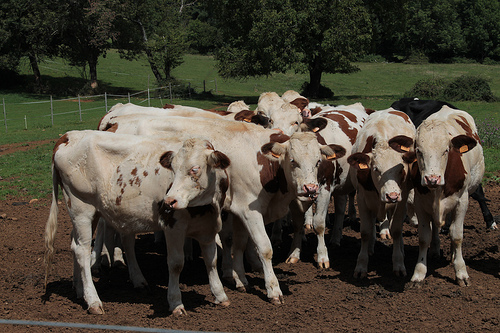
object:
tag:
[458, 145, 468, 154]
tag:
[401, 143, 411, 152]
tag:
[359, 163, 369, 169]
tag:
[325, 151, 337, 160]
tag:
[312, 127, 321, 132]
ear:
[453, 134, 478, 154]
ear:
[388, 135, 416, 154]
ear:
[347, 153, 371, 171]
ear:
[319, 145, 347, 163]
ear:
[302, 116, 327, 132]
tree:
[253, 0, 371, 100]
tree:
[116, 0, 207, 99]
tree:
[45, 0, 126, 91]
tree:
[0, 0, 67, 88]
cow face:
[166, 142, 209, 211]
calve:
[232, 92, 318, 131]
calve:
[99, 111, 331, 306]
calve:
[345, 107, 417, 280]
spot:
[130, 167, 140, 177]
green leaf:
[331, 30, 338, 37]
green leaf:
[329, 58, 341, 66]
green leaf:
[295, 56, 304, 63]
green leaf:
[269, 33, 278, 46]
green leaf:
[306, 16, 315, 26]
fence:
[0, 84, 193, 123]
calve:
[409, 104, 498, 287]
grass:
[0, 42, 500, 200]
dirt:
[0, 182, 499, 333]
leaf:
[328, 34, 335, 43]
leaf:
[246, 21, 259, 32]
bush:
[319, 84, 334, 97]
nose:
[163, 198, 177, 208]